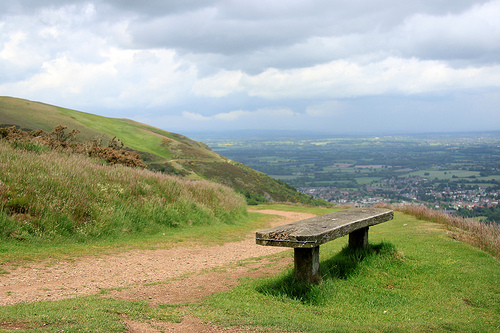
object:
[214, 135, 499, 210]
cityscape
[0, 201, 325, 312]
dirt road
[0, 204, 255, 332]
path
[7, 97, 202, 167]
grass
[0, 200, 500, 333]
field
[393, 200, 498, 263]
hillside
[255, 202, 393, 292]
bench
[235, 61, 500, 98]
cloud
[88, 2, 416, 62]
dark clouds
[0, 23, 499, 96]
sky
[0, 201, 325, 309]
road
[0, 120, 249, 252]
hillside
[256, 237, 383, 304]
shadow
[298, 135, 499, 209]
town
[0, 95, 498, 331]
hill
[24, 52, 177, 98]
clouds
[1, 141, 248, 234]
grass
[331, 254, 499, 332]
grass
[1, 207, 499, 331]
ground